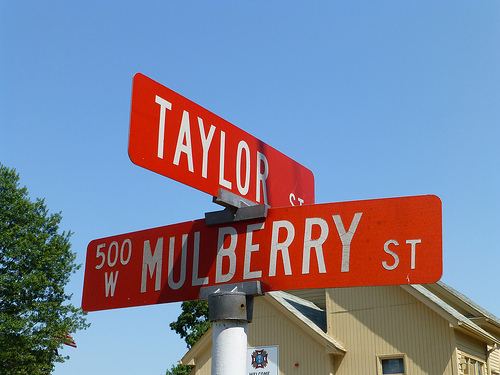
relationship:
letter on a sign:
[167, 233, 191, 294] [79, 194, 441, 313]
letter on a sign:
[378, 234, 400, 271] [79, 194, 441, 313]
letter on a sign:
[141, 240, 160, 300] [79, 194, 441, 313]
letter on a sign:
[145, 94, 173, 168] [79, 194, 441, 313]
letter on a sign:
[189, 226, 211, 288] [79, 194, 441, 313]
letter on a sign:
[211, 222, 241, 288] [79, 206, 449, 293]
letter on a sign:
[238, 219, 267, 280] [79, 194, 441, 313]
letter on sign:
[139, 237, 166, 293] [79, 194, 441, 313]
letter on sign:
[238, 219, 267, 280] [79, 194, 441, 313]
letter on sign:
[266, 218, 296, 278] [79, 194, 441, 313]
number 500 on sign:
[85, 241, 140, 281] [70, 193, 443, 298]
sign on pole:
[79, 194, 441, 313] [204, 181, 272, 373]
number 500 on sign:
[88, 238, 134, 269] [64, 201, 447, 295]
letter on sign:
[327, 210, 370, 273] [79, 194, 441, 313]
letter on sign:
[211, 222, 241, 288] [79, 194, 441, 313]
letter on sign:
[189, 226, 217, 292] [294, 216, 334, 279]